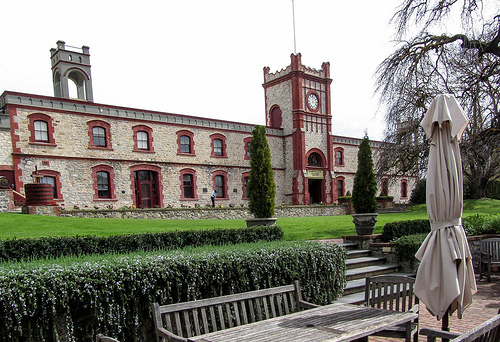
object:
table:
[187, 302, 418, 341]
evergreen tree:
[350, 127, 379, 214]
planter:
[244, 217, 277, 228]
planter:
[352, 212, 379, 235]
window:
[92, 125, 108, 147]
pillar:
[49, 39, 94, 102]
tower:
[260, 53, 339, 206]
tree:
[370, 0, 499, 201]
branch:
[394, 0, 424, 36]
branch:
[436, 28, 495, 62]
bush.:
[246, 124, 277, 218]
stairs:
[333, 243, 417, 304]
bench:
[480, 237, 500, 282]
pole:
[292, 0, 297, 53]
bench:
[151, 280, 323, 342]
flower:
[0, 239, 347, 332]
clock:
[305, 92, 323, 112]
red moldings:
[291, 125, 305, 171]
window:
[131, 163, 165, 212]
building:
[0, 40, 424, 222]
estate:
[1, 36, 424, 212]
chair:
[357, 275, 423, 342]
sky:
[0, 2, 496, 143]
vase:
[351, 212, 379, 236]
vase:
[244, 216, 277, 226]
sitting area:
[150, 273, 498, 340]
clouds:
[90, 6, 265, 54]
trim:
[293, 55, 305, 186]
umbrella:
[412, 91, 472, 321]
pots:
[243, 125, 278, 228]